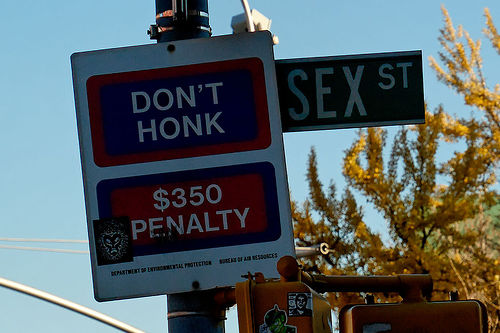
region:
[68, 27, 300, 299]
A white sign that says Don't Honk and $350 Penalty.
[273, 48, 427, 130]
Green and white sign that says SEX ST.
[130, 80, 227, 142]
White letters that say DON'T HONK.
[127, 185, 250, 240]
$350 PENALTY in white color on a sign.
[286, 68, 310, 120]
Grey letter S in SEX.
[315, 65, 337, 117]
Grey E in SEX.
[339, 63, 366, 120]
Grey X in SEX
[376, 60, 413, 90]
ST after SEX on a green sign.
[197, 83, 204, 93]
White apostrophe between N and T in Don't.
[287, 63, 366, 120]
The word SEX on a sign.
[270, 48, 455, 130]
The sign says Sex St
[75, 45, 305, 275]
The sign is red white and blue.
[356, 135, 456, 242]
The leaves on the tree is yellow.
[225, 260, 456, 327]
The traffic signal is yellow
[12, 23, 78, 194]
The sky is blue and clear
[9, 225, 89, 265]
Wires in the sky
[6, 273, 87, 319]
Part of a light post.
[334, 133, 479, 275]
Tree behind the sign.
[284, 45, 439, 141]
The sign is green and white.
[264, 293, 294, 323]
Stickers on the traffic signal.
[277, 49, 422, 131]
a red and white street sign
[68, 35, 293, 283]
a red and white street sign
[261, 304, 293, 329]
a black and white sticker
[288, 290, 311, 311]
a black and white sticker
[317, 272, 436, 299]
a yellow metal short pole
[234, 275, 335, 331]
a yellow metal box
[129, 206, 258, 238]
white capital letters of the sign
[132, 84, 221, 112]
white capital letters of the sign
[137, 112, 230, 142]
white capital letters of the sign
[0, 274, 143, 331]
a light colored metal pole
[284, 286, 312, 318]
Sticker on traffic signal casing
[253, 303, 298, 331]
Sticker on traffic signal casing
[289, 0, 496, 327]
Tree with fall colored leaves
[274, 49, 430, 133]
Street sign with humorous street name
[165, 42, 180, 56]
Bolt holding sign in place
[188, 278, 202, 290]
Bolt holding sign in place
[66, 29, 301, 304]
Citation warning sign against honking horn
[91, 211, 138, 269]
Sticker on metal sign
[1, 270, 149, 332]
Street light support pole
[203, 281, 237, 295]
Rust marks on metal sign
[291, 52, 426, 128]
street sign on pole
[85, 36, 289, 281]
street sign on pole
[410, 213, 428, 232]
leaves on the tree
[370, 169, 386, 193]
leaves on the tree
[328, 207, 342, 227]
leaves on the tree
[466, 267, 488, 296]
leaves on the tree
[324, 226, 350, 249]
leaves on the tree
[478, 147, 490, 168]
leaves on the tree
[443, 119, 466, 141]
leaves on the tree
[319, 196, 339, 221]
leaves on the tree